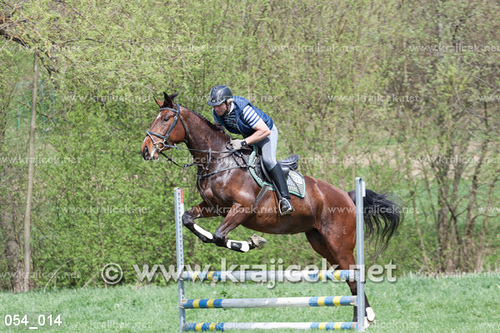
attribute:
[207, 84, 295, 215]
man — jockey, leaning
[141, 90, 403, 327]
horse — jumping, red, brown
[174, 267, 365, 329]
hurdle — metal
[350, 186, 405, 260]
tail — black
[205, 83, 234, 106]
helmet — black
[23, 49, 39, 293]
trunk — skinny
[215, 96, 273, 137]
vest — blue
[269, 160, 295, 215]
boot — black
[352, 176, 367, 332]
pole — metal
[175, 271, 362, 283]
pole — blue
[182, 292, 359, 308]
pole — yellow